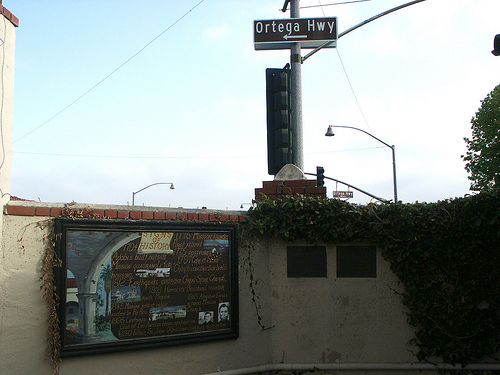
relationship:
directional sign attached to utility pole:
[250, 15, 341, 43] [284, 4, 306, 170]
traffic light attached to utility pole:
[266, 65, 297, 173] [284, 4, 306, 170]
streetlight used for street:
[323, 116, 399, 203] [331, 189, 355, 201]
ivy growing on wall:
[235, 184, 500, 369] [1, 1, 497, 374]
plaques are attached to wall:
[283, 244, 380, 280] [1, 1, 497, 374]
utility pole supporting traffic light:
[284, 4, 306, 170] [266, 65, 297, 173]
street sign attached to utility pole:
[250, 15, 341, 43] [284, 4, 306, 170]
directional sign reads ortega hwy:
[250, 15, 341, 43] [257, 21, 336, 33]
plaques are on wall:
[283, 244, 380, 280] [1, 1, 497, 374]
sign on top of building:
[47, 213, 242, 360] [1, 1, 497, 374]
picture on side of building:
[47, 213, 242, 360] [1, 1, 497, 374]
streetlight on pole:
[167, 179, 176, 190] [125, 174, 169, 209]